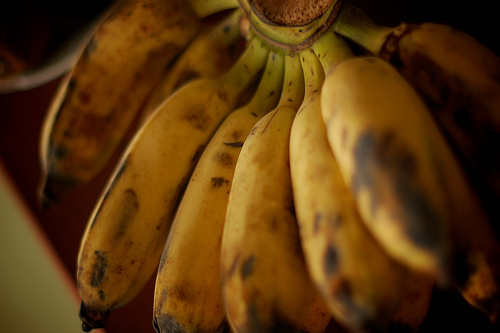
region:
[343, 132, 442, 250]
black spot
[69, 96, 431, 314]
a batch of bananas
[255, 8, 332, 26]
stem of the banana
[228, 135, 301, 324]
a banana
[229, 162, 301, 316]
the peal of the banana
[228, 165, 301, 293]
the peel is yellow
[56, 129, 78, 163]
black spots on the peel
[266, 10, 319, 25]
the stem is brown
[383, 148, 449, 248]
spots on the banana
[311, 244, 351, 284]
black spot on the banana peel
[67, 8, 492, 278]
a bunch of yellow bananas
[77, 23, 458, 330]
a bunch of banans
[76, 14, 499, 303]
yellow bananas together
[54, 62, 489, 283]
bananas turning bad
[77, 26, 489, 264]
a bun of small bananas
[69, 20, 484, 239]
a bunch of small banans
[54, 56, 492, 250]
small yellow bananas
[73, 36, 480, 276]
small yellow bananas together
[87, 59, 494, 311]
small bananas going bad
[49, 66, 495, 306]
bananas that are yelloow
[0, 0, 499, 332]
a bushel of old, rotting bananas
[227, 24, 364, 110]
stems of the bananas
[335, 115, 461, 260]
blurred black spot on peel of rightmost banana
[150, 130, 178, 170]
relatively unmolded portion of the leftmost banana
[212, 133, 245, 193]
black spots on the second-from-left banana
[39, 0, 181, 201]
banana in background of photograph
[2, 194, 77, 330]
blurred section of white flooring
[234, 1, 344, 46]
tier holding the bananas together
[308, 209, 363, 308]
black marks on the second-from-right banana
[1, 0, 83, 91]
blurred section showing a sink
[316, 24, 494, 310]
an over ripe yellow banana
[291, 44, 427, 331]
an over ripe yellow banana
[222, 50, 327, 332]
an over ripe yellow banana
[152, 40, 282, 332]
an over ripe yellow banana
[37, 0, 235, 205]
an over ripe yellow banana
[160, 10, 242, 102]
an over ripe yellow banana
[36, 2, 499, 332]
a bunch of bananas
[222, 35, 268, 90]
a green banana stem